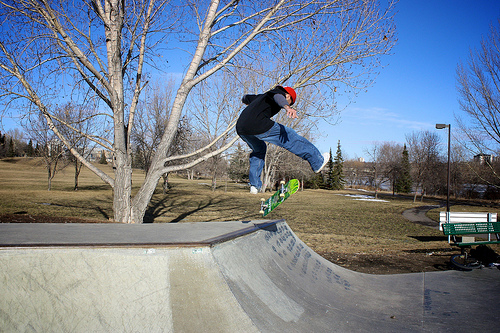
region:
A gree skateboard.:
[255, 177, 300, 216]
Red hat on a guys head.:
[278, 84, 297, 107]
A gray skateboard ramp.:
[1, 219, 498, 331]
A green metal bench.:
[440, 216, 498, 257]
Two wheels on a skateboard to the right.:
[277, 179, 287, 202]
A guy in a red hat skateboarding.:
[235, 84, 330, 196]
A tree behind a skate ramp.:
[0, 0, 399, 224]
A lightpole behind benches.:
[432, 121, 450, 212]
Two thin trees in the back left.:
[39, 97, 91, 186]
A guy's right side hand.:
[284, 105, 299, 122]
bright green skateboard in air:
[254, 175, 300, 220]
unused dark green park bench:
[440, 218, 499, 266]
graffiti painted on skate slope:
[265, 217, 355, 294]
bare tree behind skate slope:
[4, 2, 397, 227]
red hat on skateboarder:
[277, 80, 301, 108]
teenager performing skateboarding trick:
[232, 77, 333, 222]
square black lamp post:
[432, 119, 452, 223]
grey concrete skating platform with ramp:
[3, 217, 493, 322]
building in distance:
[473, 151, 497, 168]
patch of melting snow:
[340, 184, 389, 207]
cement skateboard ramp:
[1, 215, 495, 332]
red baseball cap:
[276, 81, 303, 103]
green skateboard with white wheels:
[253, 176, 309, 218]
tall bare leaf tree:
[1, 1, 400, 226]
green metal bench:
[433, 213, 499, 270]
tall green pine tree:
[388, 140, 415, 197]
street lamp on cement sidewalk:
[429, 119, 459, 220]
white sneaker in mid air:
[311, 151, 335, 176]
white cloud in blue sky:
[375, 97, 410, 124]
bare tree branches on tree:
[274, 43, 373, 69]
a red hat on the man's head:
[271, 80, 302, 105]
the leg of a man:
[250, 111, 325, 173]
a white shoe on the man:
[311, 148, 334, 177]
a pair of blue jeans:
[241, 112, 328, 189]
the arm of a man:
[270, 86, 290, 110]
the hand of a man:
[274, 99, 302, 121]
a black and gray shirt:
[231, 80, 291, 135]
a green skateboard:
[237, 169, 310, 220]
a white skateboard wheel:
[274, 187, 289, 199]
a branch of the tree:
[194, 1, 286, 87]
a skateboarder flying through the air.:
[229, 85, 332, 225]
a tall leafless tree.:
[0, 0, 395, 230]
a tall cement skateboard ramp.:
[0, 218, 497, 331]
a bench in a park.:
[428, 201, 498, 261]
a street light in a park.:
[424, 121, 456, 214]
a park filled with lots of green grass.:
[0, 149, 497, 272]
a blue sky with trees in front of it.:
[0, 4, 498, 166]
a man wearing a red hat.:
[270, 79, 300, 117]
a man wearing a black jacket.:
[225, 74, 289, 157]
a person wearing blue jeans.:
[242, 113, 327, 183]